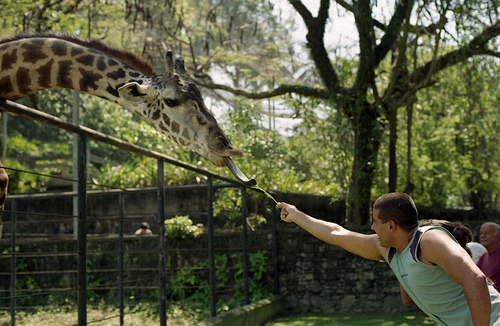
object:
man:
[470, 214, 495, 308]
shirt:
[477, 250, 498, 282]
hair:
[373, 192, 417, 232]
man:
[342, 172, 477, 215]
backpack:
[421, 205, 469, 231]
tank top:
[381, 224, 498, 322]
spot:
[106, 67, 129, 79]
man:
[373, 177, 499, 317]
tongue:
[219, 155, 256, 185]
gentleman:
[473, 213, 499, 270]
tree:
[302, 14, 457, 229]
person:
[132, 220, 156, 246]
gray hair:
[484, 219, 499, 230]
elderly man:
[475, 216, 499, 274]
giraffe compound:
[1, 28, 289, 323]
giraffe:
[0, 28, 257, 207]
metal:
[75, 195, 206, 293]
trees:
[253, 16, 487, 186]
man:
[266, 170, 487, 324]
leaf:
[246, 180, 283, 205]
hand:
[273, 194, 298, 227]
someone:
[269, 188, 499, 325]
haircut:
[376, 195, 415, 224]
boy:
[275, 191, 499, 323]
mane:
[121, 45, 132, 72]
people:
[276, 193, 488, 323]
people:
[452, 207, 495, 277]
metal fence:
[1, 97, 278, 324]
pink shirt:
[483, 252, 499, 278]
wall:
[246, 180, 356, 314]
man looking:
[133, 222, 155, 239]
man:
[270, 188, 495, 322]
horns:
[159, 44, 189, 74]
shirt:
[372, 224, 490, 322]